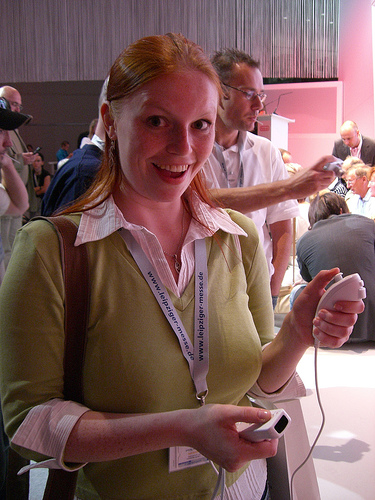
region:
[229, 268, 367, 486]
THIS IS A CONTROLLER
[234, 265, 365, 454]
THE CONTROLLER IS WHITE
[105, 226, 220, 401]
THE GIRL IS WEARING A LANYARD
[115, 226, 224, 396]
THIS IS A LANYARD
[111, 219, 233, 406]
THE LANYARD IS WHITE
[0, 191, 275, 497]
THE SWEATER IS V-NECK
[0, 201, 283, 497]
THE SWEATER IS GREEN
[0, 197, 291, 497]
THE GIRL IS WEARING A SWEATER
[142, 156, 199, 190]
THE GIRL IS SMILING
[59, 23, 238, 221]
THE GIRL HAS RED HAIR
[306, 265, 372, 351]
the remote is white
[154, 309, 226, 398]
the tag is around the womans neck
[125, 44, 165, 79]
the woman has red hair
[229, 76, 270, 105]
the man is wearing glasses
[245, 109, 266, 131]
the toothpick is in the mans mouth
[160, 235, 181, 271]
the woman is wearing a necklace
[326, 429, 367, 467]
the shadow is on the ground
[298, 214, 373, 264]
the shirt is black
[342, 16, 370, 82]
the wall is pink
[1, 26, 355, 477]
the woman is smiling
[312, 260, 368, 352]
a white game controller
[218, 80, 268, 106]
a man's eyeglasses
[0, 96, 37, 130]
part of a black baseball cap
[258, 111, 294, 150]
part of white podium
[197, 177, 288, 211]
the arm of a man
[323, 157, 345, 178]
a digital camera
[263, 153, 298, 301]
the arm of a man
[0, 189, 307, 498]
a woman's collared shirt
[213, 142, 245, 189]
part of a gray lanyard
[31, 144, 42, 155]
a black cellphone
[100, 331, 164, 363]
Small part of a green shirt of the lady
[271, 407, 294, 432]
Top of the Wii remote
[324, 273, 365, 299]
A white Wii nunchuck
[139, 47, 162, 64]
Small patch of the lady's red hair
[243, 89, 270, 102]
Glasses of the man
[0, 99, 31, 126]
Black cap of the man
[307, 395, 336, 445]
White cord that connects the Wii remote and the nunchuck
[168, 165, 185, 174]
White teeth of the female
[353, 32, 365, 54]
Red wall in the room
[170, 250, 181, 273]
Gray necklace on the woman's neck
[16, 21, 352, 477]
woman holding a white Wii controller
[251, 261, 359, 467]
white Wii game controller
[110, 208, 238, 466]
black and white lanyard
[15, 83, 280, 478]
woman wearing a green sweater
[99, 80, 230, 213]
face of a smiling woman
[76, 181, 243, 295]
collar of a white woman's shirt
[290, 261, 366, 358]
hand of a woman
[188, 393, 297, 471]
hand of a woman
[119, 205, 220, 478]
name badge on a white lanyard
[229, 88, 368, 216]
people in the background